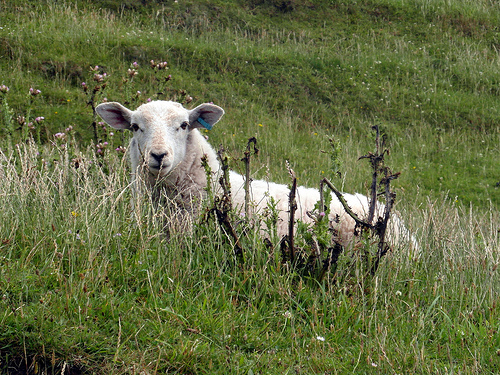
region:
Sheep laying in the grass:
[94, 97, 425, 288]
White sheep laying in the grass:
[92, 99, 422, 275]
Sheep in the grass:
[93, 98, 423, 280]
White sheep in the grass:
[95, 96, 425, 282]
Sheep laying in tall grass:
[95, 99, 426, 298]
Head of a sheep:
[97, 95, 227, 177]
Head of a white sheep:
[94, 96, 225, 176]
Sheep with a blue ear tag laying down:
[92, 96, 424, 287]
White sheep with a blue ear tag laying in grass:
[92, 96, 421, 284]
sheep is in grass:
[124, 91, 391, 285]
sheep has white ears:
[82, 107, 233, 137]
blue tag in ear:
[160, 101, 212, 131]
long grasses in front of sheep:
[202, 133, 457, 327]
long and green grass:
[264, 45, 405, 157]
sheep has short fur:
[211, 134, 368, 245]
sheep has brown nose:
[144, 144, 168, 178]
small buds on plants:
[7, 50, 161, 150]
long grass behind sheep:
[25, 10, 350, 67]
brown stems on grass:
[12, 143, 126, 213]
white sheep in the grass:
[92, 93, 430, 275]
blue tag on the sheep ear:
[97, 99, 229, 188]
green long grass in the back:
[237, 6, 474, 118]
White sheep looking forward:
[93, 93, 431, 269]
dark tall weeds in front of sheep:
[197, 127, 403, 277]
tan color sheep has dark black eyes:
[93, 99, 411, 269]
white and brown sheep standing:
[91, 97, 421, 267]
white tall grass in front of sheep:
[0, 140, 128, 312]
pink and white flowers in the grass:
[0, 38, 92, 203]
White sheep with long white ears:
[96, 94, 417, 274]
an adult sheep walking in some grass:
[95, 82, 497, 242]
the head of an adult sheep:
[97, 88, 227, 188]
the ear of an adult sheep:
[92, 92, 129, 136]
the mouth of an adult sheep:
[144, 136, 171, 167]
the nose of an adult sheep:
[151, 143, 166, 161]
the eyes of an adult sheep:
[124, 113, 196, 134]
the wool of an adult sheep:
[180, 145, 208, 185]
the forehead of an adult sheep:
[140, 102, 180, 136]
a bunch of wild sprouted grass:
[95, 263, 206, 348]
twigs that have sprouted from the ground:
[327, 128, 407, 270]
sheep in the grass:
[86, 95, 414, 255]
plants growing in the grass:
[217, 172, 377, 292]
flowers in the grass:
[41, 53, 170, 84]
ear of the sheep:
[194, 105, 221, 126]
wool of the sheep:
[264, 193, 324, 213]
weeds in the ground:
[33, 181, 122, 228]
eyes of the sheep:
[131, 114, 194, 138]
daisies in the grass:
[102, 20, 162, 45]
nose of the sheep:
[142, 150, 167, 162]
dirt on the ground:
[49, 355, 149, 369]